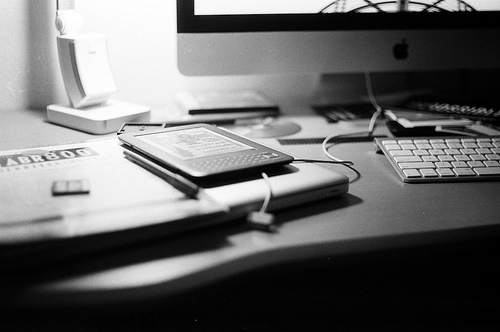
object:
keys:
[402, 166, 420, 176]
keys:
[455, 166, 476, 176]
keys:
[440, 166, 456, 176]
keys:
[474, 167, 497, 174]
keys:
[383, 138, 400, 147]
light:
[139, 23, 171, 74]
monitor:
[173, 0, 499, 80]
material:
[0, 138, 194, 230]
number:
[400, 164, 409, 169]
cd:
[220, 117, 303, 138]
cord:
[260, 73, 383, 214]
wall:
[0, 0, 168, 117]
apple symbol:
[388, 38, 412, 60]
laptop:
[0, 125, 349, 268]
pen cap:
[164, 172, 203, 200]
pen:
[121, 146, 206, 200]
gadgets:
[4, 7, 499, 304]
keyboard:
[371, 136, 499, 185]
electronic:
[369, 136, 497, 187]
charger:
[245, 64, 380, 229]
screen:
[133, 125, 255, 160]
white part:
[177, 29, 499, 77]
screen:
[196, 0, 498, 15]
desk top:
[0, 94, 499, 303]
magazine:
[0, 139, 183, 247]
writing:
[0, 148, 95, 173]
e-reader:
[117, 123, 292, 184]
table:
[0, 99, 499, 311]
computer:
[176, 0, 498, 121]